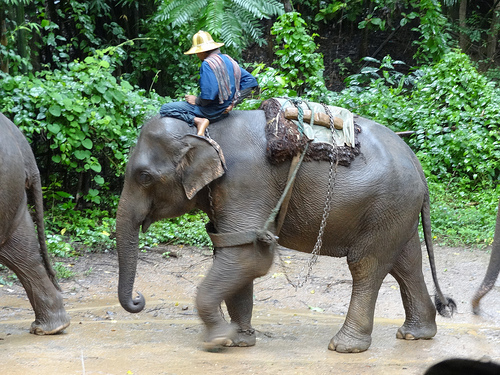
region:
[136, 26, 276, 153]
Man sitting on an elephant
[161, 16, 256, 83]
Wearing a safari hat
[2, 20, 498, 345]
Three elephants walking in line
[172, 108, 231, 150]
No shoes on feet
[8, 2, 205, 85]
Greenery in the background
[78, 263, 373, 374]
Walking in mud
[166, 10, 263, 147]
Wearing a blue shirt and blue pants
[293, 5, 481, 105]
Dark shadow in woods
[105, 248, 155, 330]
Elephant's trunk is curled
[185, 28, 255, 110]
Scarf around neck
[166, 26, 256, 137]
person riding an elephant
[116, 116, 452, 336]
a gray elephant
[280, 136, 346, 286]
a silver chain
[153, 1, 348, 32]
a tropical tree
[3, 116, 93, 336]
the tail and paw of an elephant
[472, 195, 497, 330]
the trunk of an elephant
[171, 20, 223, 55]
a person wearing a straw hat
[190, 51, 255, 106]
a person wearing blue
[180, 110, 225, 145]
a person wearing no shoes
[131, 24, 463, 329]
a person sitting on top of an elepant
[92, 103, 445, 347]
the elephant is gray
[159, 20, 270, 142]
a man is sitting on the elephant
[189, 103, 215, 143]
the man is barefoot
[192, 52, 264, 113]
the man is wearing a blue shirt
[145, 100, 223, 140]
the man is wearing blue pants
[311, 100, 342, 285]
a chain on the elephant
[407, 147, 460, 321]
the elephant's long tail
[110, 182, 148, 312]
the elephant's curled trunk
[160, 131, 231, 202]
the elephant's large ear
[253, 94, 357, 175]
a blanket on the elephant's back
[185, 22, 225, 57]
man's yellow hat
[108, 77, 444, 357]
elephant walking between two others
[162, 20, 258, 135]
man riding elephant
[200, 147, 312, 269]
leather harness for elephant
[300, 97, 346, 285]
chain securing load on elephant's back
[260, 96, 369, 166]
laod on elephant's back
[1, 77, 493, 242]
bushes along the pathway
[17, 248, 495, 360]
wet dirt pathway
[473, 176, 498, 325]
elephant's trunk of following elephant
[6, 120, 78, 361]
back leg of leading elephant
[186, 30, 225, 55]
a straw hat on a man's head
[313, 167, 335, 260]
a chain hanging down an elephant's side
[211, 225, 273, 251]
the strap of a harness on an elephant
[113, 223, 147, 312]
an elephant's trunk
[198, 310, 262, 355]
the chained front feet of an elephant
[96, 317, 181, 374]
an area of med being walked on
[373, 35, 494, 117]
an area of forest behind the elephants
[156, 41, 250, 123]
a man in blue sitting on top of an elephant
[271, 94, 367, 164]
the saddle on the back of an elephant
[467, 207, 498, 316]
an elephant's trunk entering the right side of the frame